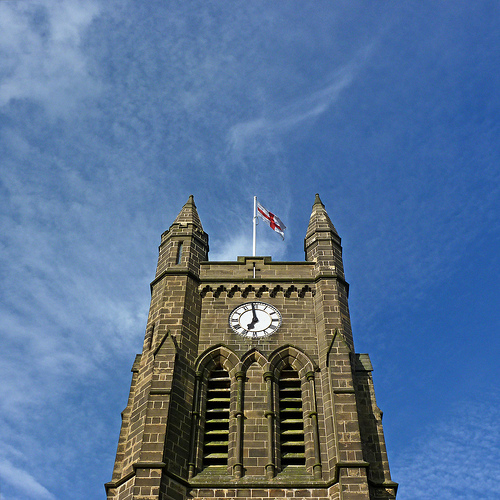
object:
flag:
[254, 197, 286, 242]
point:
[305, 192, 334, 228]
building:
[105, 194, 401, 499]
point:
[172, 195, 203, 228]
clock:
[228, 301, 280, 339]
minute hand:
[250, 303, 259, 323]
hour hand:
[246, 319, 258, 333]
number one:
[263, 305, 268, 313]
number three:
[271, 318, 280, 323]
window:
[279, 368, 305, 469]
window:
[202, 371, 231, 467]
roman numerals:
[231, 318, 238, 322]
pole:
[251, 194, 258, 257]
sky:
[329, 0, 497, 188]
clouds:
[1, 2, 114, 91]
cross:
[258, 208, 283, 235]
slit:
[279, 376, 300, 384]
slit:
[281, 395, 305, 404]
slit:
[282, 405, 302, 414]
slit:
[279, 416, 302, 426]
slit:
[285, 439, 305, 447]